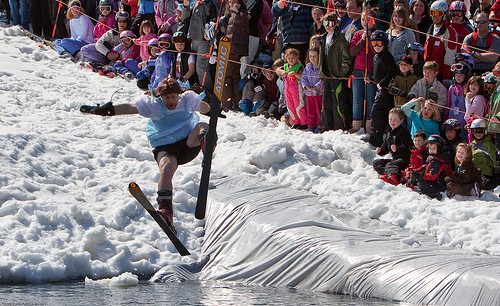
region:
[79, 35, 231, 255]
Someone wearing skis in midair.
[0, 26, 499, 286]
Snow.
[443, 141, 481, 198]
A child spectator.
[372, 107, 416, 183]
A child spectator.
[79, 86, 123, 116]
A glove.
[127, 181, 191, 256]
A ski on the man's right foot.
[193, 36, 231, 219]
A ski on the man's left foot.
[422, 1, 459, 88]
A spectator watching the skier.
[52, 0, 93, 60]
A spectator watching the skier.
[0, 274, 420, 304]
A body of water.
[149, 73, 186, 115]
the head of the person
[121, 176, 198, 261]
a black and orange ski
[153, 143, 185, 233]
the leg of the person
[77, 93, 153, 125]
the arm of the person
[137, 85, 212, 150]
a white and blue shirt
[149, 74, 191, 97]
red hair of the person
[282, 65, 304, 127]
a pink pair of pants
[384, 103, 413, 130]
the head of the boy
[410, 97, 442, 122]
the head of the girl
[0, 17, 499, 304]
white snow on the ground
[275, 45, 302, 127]
a person is watching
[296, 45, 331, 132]
a person is watching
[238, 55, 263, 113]
a person is watching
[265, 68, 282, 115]
a person is watching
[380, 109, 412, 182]
a person is watching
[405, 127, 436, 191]
a person is watching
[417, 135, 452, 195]
a person is watching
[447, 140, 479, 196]
a person is watching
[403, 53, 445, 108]
a person is watching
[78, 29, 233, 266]
The man in the air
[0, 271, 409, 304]
The water below the man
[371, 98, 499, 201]
The children in front of the fence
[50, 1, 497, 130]
The black and orange fence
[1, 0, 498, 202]
The spectators watching the man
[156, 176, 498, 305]
The white tarp on the snow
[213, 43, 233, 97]
The word 'Atomic'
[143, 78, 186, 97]
The wig on the man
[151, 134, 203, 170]
The black shorts the man is wearing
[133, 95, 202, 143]
The blue dress worn by the man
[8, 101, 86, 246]
White snow on slope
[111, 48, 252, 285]
Man wearing skis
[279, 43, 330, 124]
Children watching skier behind a rope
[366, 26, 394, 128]
Kid in black wearing a helmet and goggles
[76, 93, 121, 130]
Black glove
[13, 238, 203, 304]
Water at the bottom of slope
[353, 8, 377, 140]
Black and orange pole holding ropes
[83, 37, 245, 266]
Skier jumping over water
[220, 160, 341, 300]
Plastic sheeting going into the water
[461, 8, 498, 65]
Man watching with arms folded